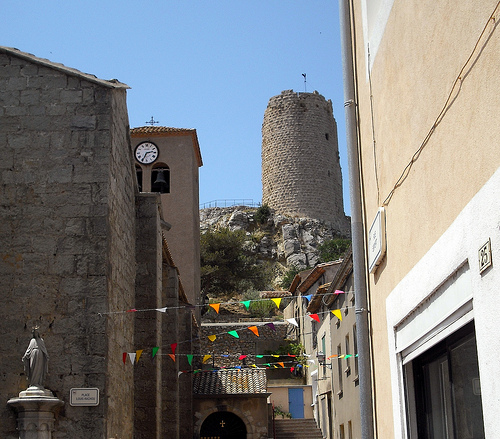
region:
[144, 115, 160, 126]
cross on top of building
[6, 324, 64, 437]
statue and pedestal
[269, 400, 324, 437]
concrete stairway and handrail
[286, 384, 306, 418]
blue door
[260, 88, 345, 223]
block tower on top of hill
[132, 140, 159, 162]
white clock with black numerals and hands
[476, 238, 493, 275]
number on front of building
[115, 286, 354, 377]
multi-colored hanging flags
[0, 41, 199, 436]
grey concrete block structure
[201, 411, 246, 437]
wooden door with golden cross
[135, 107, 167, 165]
Here is clocktower.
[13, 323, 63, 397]
A statue on a column post.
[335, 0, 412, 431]
A drain pipe from the gutter.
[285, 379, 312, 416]
A blue door.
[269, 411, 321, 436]
Stairs up to the blue door.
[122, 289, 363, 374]
Flags hanging over the alley.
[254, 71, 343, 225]
A brick tower for sightseeing.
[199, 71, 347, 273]
The rock cliff in front of the brick tower.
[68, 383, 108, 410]
A sign on the building.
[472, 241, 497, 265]
The number for the address of the building.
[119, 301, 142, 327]
Colorful flag handing on rope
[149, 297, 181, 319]
Colorful flag handing on rope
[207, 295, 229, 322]
Colorful flag handing on rope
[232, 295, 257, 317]
Colorful flag handing on rope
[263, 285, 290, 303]
Colorful flag handing on rope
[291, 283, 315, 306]
Colorful flag handing on rope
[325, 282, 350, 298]
Colorful flag handing on rope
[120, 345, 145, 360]
Colorful flag handing on rope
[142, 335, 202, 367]
Colorful flag handing on rope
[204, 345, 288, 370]
Colorful flag handing on rope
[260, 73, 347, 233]
a castle keep on the grass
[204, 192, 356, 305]
the hill is steep and rocky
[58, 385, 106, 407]
a street sign on the wall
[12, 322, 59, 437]
a statue by the sign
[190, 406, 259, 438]
an arched doorway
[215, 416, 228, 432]
a gold cross on the doorway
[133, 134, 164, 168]
a clock on a tower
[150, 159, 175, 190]
a bell under the clock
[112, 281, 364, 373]
flags across the street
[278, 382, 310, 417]
a blue door in a wall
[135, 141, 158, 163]
the clock on the tower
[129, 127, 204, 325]
the clock tower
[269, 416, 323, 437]
the stairs on the building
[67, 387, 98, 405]
the sign on the building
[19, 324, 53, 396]
the statue on the stand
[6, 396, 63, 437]
the stand for the statue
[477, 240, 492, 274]
the number 25 on the building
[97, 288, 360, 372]
the colorful triangle flags hanging between the buildings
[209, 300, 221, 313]
the orange triangle flag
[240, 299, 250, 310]
the green triangle flag